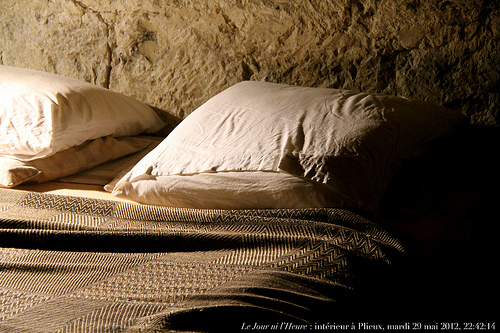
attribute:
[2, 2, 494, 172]
stone wall — rough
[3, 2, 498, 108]
wall — stone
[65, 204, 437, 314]
quilt — thin, brown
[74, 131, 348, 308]
bed — unmade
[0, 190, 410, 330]
blanket — knitted, grey, brown 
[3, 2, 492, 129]
wall — natural grey stone